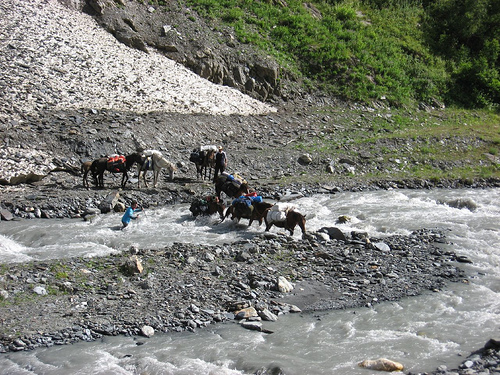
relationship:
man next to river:
[104, 185, 140, 245] [51, 192, 132, 295]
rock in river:
[22, 185, 98, 245] [51, 192, 132, 295]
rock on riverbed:
[22, 185, 98, 245] [51, 192, 132, 295]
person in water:
[104, 185, 140, 245] [45, 212, 125, 278]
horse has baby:
[138, 145, 175, 184] [182, 141, 219, 162]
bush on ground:
[382, 81, 425, 108] [257, 53, 434, 231]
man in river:
[119, 197, 142, 229] [51, 192, 132, 295]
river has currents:
[51, 192, 132, 295] [1, 209, 92, 265]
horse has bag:
[138, 145, 175, 184] [107, 153, 126, 163]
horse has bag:
[138, 145, 175, 184] [105, 144, 139, 164]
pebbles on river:
[22, 200, 150, 261] [51, 192, 132, 295]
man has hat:
[104, 185, 140, 245] [121, 198, 146, 209]